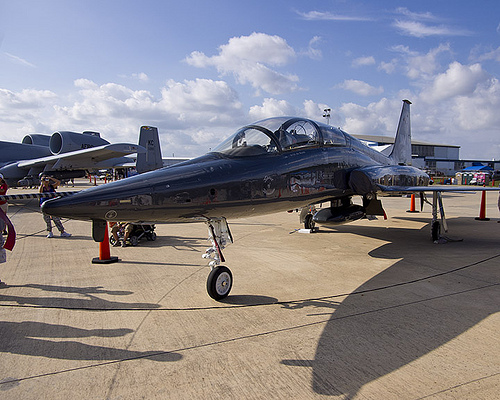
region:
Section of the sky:
[125, 68, 231, 118]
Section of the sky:
[236, 35, 316, 83]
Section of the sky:
[65, 45, 140, 111]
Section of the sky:
[3, 58, 65, 126]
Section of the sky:
[412, 50, 497, 113]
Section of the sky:
[330, 52, 385, 127]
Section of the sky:
[246, 75, 320, 107]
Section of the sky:
[193, 78, 241, 118]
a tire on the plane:
[207, 263, 228, 296]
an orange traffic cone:
[86, 220, 116, 265]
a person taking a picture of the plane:
[35, 171, 70, 233]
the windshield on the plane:
[230, 110, 307, 150]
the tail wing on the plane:
[385, 95, 417, 150]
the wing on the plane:
[370, 170, 495, 205]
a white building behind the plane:
[395, 145, 460, 165]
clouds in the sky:
[65, 67, 245, 117]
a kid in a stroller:
[107, 216, 154, 246]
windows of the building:
[411, 145, 431, 151]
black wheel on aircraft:
[196, 263, 247, 307]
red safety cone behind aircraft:
[90, 216, 120, 267]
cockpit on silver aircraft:
[215, 108, 348, 163]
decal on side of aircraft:
[252, 167, 282, 205]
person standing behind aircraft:
[28, 167, 83, 254]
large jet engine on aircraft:
[21, 126, 115, 160]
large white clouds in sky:
[166, 26, 307, 115]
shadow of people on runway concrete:
[1, 269, 197, 389]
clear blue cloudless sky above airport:
[1, 0, 168, 59]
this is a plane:
[24, 69, 477, 271]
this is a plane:
[11, 120, 110, 200]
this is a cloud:
[217, 47, 296, 109]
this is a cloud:
[166, 53, 229, 137]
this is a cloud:
[324, 95, 394, 147]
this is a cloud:
[411, 56, 480, 104]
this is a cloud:
[72, 78, 129, 124]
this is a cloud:
[164, 80, 211, 125]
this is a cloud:
[25, 77, 71, 124]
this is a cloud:
[454, 94, 495, 148]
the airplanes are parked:
[1, 99, 499, 301]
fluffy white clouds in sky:
[0, 33, 499, 150]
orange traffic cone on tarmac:
[89, 215, 119, 266]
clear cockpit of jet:
[206, 113, 347, 158]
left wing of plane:
[0, 141, 147, 183]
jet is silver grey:
[39, 96, 499, 298]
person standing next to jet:
[35, 171, 72, 240]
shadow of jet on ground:
[280, 204, 498, 395]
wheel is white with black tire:
[206, 265, 233, 301]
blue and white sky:
[126, 29, 272, 132]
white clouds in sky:
[118, 11, 268, 106]